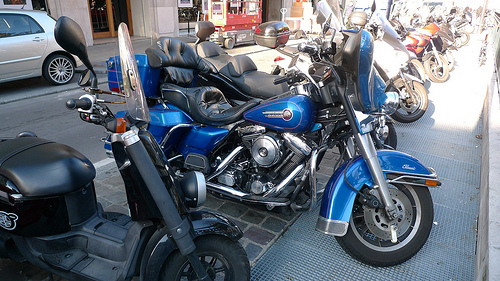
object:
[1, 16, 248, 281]
motorcycles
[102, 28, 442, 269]
motorcycle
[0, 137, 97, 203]
seat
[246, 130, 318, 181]
engine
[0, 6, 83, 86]
car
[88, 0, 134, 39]
double door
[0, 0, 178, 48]
building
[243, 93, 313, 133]
gas tank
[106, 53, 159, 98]
blue box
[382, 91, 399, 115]
headlight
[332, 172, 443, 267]
wheel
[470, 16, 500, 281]
wall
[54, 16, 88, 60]
side mirror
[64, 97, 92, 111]
handle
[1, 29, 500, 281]
road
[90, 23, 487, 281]
sidewalk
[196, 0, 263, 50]
cart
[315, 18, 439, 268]
front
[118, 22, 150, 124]
windshield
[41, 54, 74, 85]
wheel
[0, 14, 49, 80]
door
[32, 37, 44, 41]
handle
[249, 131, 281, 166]
part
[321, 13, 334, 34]
side mirror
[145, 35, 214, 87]
backrest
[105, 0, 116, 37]
wood border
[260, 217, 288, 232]
small bricks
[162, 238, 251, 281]
tire